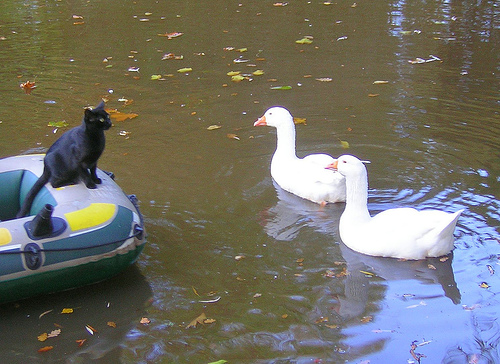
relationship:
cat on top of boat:
[17, 101, 113, 219] [1, 148, 151, 298]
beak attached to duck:
[246, 110, 264, 129] [248, 90, 346, 214]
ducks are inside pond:
[242, 95, 457, 270] [319, 47, 460, 149]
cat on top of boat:
[40, 96, 111, 194] [1, 148, 151, 298]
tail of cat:
[20, 166, 49, 230] [31, 92, 126, 205]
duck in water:
[253, 107, 371, 208] [297, 279, 427, 361]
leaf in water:
[181, 52, 267, 90] [218, 249, 317, 318]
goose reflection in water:
[265, 183, 342, 245] [5, 3, 498, 360]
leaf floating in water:
[355, 310, 376, 321] [5, 3, 498, 360]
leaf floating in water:
[185, 311, 208, 329] [5, 3, 498, 360]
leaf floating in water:
[132, 311, 153, 327] [5, 3, 498, 360]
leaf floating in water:
[81, 325, 102, 341] [5, 3, 498, 360]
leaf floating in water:
[70, 336, 90, 354] [5, 3, 498, 360]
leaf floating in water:
[33, 305, 51, 317] [5, 3, 498, 360]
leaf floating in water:
[44, 327, 60, 337] [5, 3, 498, 360]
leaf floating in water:
[28, 329, 51, 345] [5, 3, 498, 360]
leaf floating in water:
[33, 345, 60, 357] [5, 3, 498, 360]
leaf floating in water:
[104, 100, 142, 134] [5, 3, 498, 360]